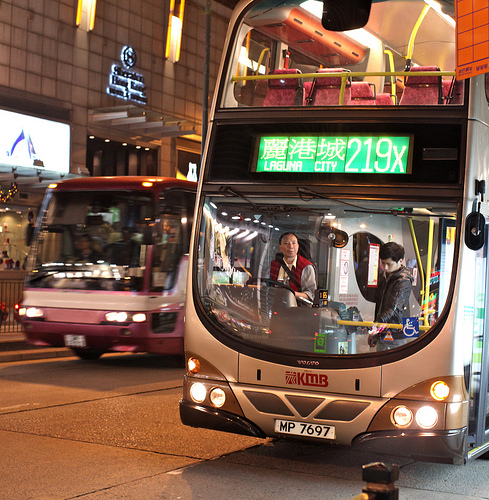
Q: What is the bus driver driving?
A: The bus driver is driving the bus.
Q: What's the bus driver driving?
A: The bus driver is driving the bus.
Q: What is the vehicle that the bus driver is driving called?
A: The vehicle is a bus.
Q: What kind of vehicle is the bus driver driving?
A: The bus driver is driving the bus.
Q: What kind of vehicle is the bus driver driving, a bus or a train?
A: The bus driver is driving a bus.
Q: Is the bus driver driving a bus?
A: Yes, the bus driver is driving a bus.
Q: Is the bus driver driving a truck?
A: No, the bus driver is driving a bus.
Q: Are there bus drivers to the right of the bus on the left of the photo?
A: Yes, there is a bus driver to the right of the bus.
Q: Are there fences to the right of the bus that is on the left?
A: No, there is a bus driver to the right of the bus.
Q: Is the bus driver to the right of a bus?
A: Yes, the bus driver is to the right of a bus.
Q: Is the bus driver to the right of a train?
A: No, the bus driver is to the right of a bus.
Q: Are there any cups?
A: No, there are no cups.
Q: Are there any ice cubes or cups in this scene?
A: No, there are no cups or ice cubes.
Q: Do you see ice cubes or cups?
A: No, there are no cups or ice cubes.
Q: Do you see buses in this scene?
A: Yes, there is a bus.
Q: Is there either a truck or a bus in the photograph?
A: Yes, there is a bus.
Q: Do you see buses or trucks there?
A: Yes, there is a bus.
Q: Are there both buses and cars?
A: No, there is a bus but no cars.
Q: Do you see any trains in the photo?
A: No, there are no trains.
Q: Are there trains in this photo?
A: No, there are no trains.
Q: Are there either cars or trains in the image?
A: No, there are no trains or cars.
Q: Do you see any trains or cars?
A: No, there are no trains or cars.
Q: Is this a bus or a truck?
A: This is a bus.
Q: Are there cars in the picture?
A: No, there are no cars.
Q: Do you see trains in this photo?
A: No, there are no trains.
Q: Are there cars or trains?
A: No, there are no trains or cars.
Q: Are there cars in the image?
A: No, there are no cars.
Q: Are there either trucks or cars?
A: No, there are no cars or trucks.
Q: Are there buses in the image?
A: Yes, there is a bus.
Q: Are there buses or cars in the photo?
A: Yes, there is a bus.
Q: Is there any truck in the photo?
A: No, there are no trucks.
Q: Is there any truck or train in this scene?
A: No, there are no trucks or trains.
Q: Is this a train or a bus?
A: This is a bus.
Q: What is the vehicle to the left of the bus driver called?
A: The vehicle is a bus.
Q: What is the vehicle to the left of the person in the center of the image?
A: The vehicle is a bus.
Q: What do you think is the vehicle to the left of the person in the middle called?
A: The vehicle is a bus.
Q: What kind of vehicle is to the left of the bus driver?
A: The vehicle is a bus.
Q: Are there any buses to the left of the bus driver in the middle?
A: Yes, there is a bus to the left of the bus driver.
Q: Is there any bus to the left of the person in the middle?
A: Yes, there is a bus to the left of the bus driver.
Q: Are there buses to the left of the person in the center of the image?
A: Yes, there is a bus to the left of the bus driver.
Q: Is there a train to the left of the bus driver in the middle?
A: No, there is a bus to the left of the bus driver.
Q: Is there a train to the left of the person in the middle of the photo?
A: No, there is a bus to the left of the bus driver.